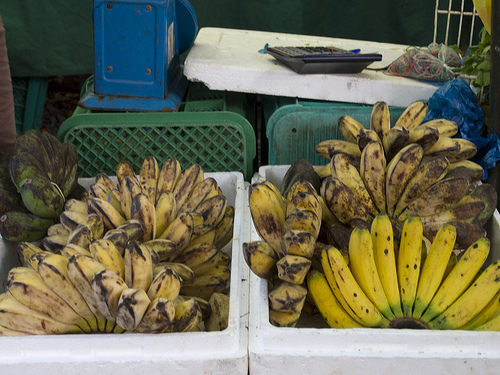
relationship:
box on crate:
[78, 59, 179, 120] [45, 112, 263, 198]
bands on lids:
[391, 50, 460, 93] [184, 99, 224, 101]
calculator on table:
[272, 49, 381, 97] [84, 98, 253, 127]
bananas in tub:
[294, 148, 491, 325] [227, 243, 471, 373]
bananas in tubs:
[49, 148, 260, 338] [63, 171, 444, 372]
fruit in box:
[284, 148, 494, 314] [228, 161, 418, 372]